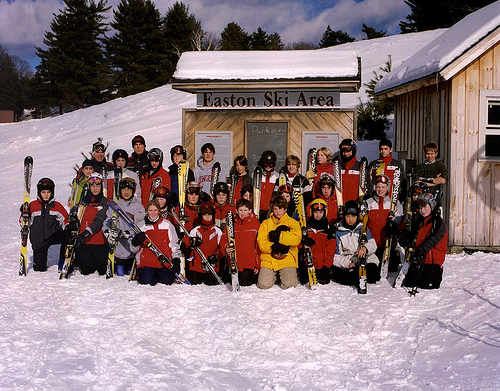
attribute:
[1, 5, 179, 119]
tree — green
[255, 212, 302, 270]
jacket — yellow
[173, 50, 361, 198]
building — white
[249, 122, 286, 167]
door — grey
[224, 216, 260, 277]
jacket — red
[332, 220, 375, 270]
coat — white